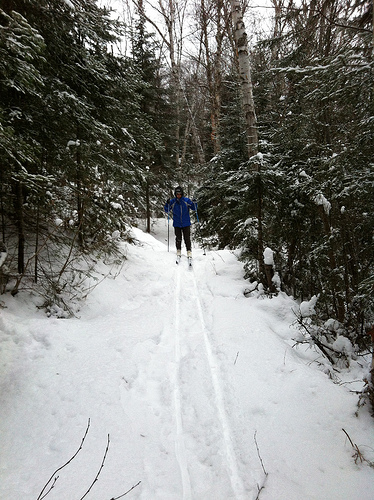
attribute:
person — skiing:
[167, 176, 197, 260]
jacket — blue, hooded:
[169, 195, 190, 225]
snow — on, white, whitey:
[174, 430, 193, 455]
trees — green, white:
[124, 74, 171, 124]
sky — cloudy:
[153, 20, 199, 48]